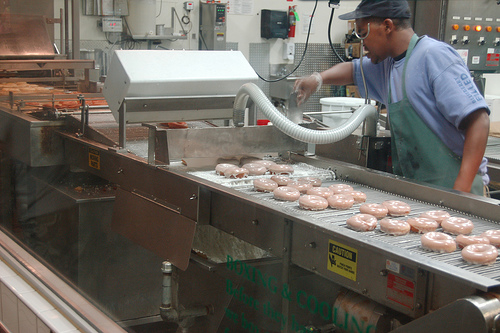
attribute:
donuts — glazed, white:
[216, 160, 500, 264]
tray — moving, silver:
[187, 157, 500, 283]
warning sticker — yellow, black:
[325, 238, 359, 283]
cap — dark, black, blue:
[339, 1, 412, 20]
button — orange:
[451, 23, 461, 31]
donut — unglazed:
[166, 118, 188, 128]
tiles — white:
[1, 260, 82, 332]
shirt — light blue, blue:
[352, 33, 491, 184]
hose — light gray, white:
[233, 82, 378, 145]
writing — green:
[224, 254, 382, 332]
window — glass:
[2, 1, 500, 331]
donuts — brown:
[1, 81, 107, 110]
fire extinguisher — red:
[289, 3, 297, 38]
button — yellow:
[464, 23, 471, 31]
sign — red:
[387, 276, 416, 309]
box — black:
[260, 8, 289, 38]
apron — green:
[386, 101, 453, 183]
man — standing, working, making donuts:
[354, 0, 488, 192]